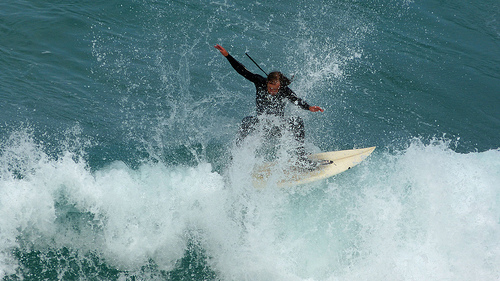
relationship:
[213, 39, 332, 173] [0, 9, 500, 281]
man riding a waves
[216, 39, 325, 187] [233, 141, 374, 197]
man balancing on surfboard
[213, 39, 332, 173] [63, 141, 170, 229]
man surfing wave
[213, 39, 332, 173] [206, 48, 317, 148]
man in wet suit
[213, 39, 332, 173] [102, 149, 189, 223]
man surfing waves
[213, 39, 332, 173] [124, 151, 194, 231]
man surfing waves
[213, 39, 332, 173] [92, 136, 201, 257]
man surfing waves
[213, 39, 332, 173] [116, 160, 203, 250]
man surfing waves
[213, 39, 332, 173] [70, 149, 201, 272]
man surfing waves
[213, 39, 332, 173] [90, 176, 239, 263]
man surfing waves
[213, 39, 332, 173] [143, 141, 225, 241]
man surfing waves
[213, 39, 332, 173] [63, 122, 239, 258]
man surfing waves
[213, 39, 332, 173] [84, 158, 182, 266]
man surfing waves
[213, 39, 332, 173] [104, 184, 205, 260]
man surfing waves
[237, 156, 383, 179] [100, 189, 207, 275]
surfboard on wave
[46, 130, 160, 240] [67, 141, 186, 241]
water in ocean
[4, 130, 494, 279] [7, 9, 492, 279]
foam from ocean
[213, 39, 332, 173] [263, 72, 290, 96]
man has head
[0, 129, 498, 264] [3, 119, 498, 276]
crest of a wave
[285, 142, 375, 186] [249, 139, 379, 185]
front end of a surfboard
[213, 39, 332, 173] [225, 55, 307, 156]
man wearing wetsuit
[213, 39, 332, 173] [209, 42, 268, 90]
man has arm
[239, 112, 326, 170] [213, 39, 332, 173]
legs of a man